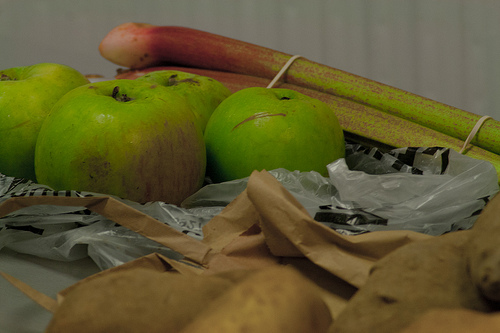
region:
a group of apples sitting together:
[6, 56, 328, 206]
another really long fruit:
[99, 17, 497, 171]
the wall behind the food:
[205, 7, 492, 110]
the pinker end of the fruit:
[91, 19, 281, 97]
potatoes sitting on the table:
[38, 204, 498, 331]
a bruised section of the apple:
[116, 132, 207, 199]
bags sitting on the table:
[13, 138, 481, 290]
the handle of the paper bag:
[0, 188, 210, 298]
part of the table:
[0, 252, 76, 329]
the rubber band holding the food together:
[450, 96, 492, 161]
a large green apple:
[195, 67, 344, 188]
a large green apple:
[28, 71, 200, 216]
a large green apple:
[129, 52, 240, 134]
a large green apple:
[1, 56, 97, 188]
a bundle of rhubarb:
[95, 15, 499, 182]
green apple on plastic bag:
[190, 73, 351, 195]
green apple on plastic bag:
[23, 62, 210, 218]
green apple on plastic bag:
[125, 64, 240, 139]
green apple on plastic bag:
[0, 49, 97, 190]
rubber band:
[238, 45, 317, 106]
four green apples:
[3, 53, 328, 193]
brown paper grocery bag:
[22, 196, 497, 330]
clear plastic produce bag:
[349, 143, 471, 218]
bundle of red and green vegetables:
[125, 20, 494, 151]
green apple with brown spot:
[38, 71, 193, 206]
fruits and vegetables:
[11, 32, 493, 195]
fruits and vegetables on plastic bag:
[3, 26, 463, 263]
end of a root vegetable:
[99, 20, 259, 77]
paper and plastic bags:
[223, 164, 463, 331]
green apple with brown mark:
[208, 82, 346, 177]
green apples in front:
[14, 67, 319, 190]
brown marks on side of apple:
[81, 116, 199, 225]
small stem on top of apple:
[251, 41, 321, 113]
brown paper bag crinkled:
[141, 177, 355, 307]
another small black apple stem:
[106, 83, 154, 105]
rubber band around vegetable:
[264, 45, 312, 85]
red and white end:
[33, 24, 319, 90]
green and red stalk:
[347, 42, 478, 168]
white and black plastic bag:
[190, 147, 447, 267]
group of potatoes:
[262, 220, 441, 324]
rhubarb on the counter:
[121, 20, 311, 92]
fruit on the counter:
[9, 27, 490, 194]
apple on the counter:
[225, 78, 352, 172]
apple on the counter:
[52, 81, 199, 216]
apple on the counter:
[155, 58, 215, 115]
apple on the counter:
[2, 57, 45, 139]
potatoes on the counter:
[102, 239, 484, 331]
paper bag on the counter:
[239, 192, 381, 289]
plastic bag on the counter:
[338, 166, 457, 217]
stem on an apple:
[107, 82, 154, 124]